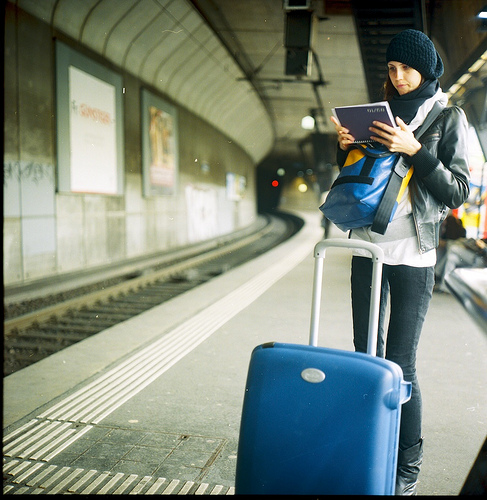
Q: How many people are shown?
A: One.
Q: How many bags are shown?
A: Two.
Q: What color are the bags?
A: Blue.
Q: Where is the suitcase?
A: The ground.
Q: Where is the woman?
A: The train station.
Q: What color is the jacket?
A: Black.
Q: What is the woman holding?
A: A tablet.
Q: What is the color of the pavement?
A: Gray.